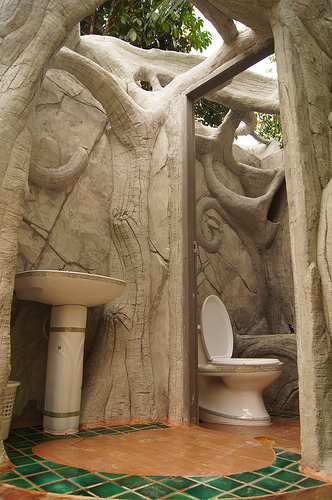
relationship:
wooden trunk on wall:
[50, 46, 171, 423] [1, 0, 188, 425]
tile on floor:
[4, 412, 321, 497] [0, 403, 317, 497]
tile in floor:
[107, 420, 135, 433] [0, 403, 317, 497]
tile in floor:
[112, 425, 137, 434] [6, 421, 321, 495]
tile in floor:
[93, 425, 115, 436] [3, 407, 320, 493]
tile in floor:
[50, 432, 77, 441] [3, 407, 320, 493]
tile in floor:
[25, 431, 50, 440] [3, 407, 320, 493]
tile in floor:
[8, 438, 36, 449] [0, 403, 317, 497]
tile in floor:
[13, 460, 48, 475] [3, 407, 320, 493]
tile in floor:
[24, 471, 65, 486] [2, 418, 330, 498]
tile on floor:
[24, 471, 65, 486] [2, 418, 330, 498]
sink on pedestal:
[10, 261, 127, 307] [39, 299, 89, 435]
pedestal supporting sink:
[37, 306, 88, 435] [13, 266, 130, 306]